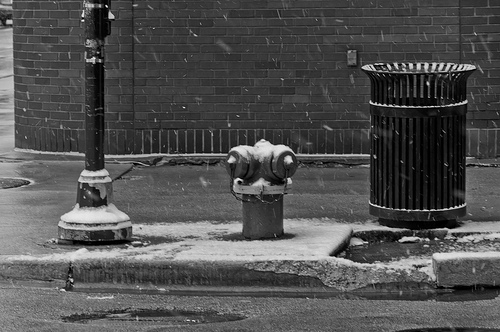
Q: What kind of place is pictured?
A: It is a sidewalk.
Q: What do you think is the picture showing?
A: It is showing a sidewalk.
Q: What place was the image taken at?
A: It was taken at the sidewalk.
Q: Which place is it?
A: It is a sidewalk.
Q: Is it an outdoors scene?
A: Yes, it is outdoors.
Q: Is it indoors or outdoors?
A: It is outdoors.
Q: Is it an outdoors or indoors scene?
A: It is outdoors.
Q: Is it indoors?
A: No, it is outdoors.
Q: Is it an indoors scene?
A: No, it is outdoors.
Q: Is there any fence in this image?
A: No, there are no fences.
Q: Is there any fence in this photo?
A: No, there are no fences.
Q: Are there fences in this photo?
A: No, there are no fences.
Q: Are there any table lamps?
A: No, there are no table lamps.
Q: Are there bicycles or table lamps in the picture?
A: No, there are no table lamps or bicycles.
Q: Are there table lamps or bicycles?
A: No, there are no table lamps or bicycles.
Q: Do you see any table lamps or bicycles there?
A: No, there are no table lamps or bicycles.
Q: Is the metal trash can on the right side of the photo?
A: Yes, the garbage bin is on the right of the image.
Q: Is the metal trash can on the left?
A: No, the trash bin is on the right of the image.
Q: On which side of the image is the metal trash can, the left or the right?
A: The garbage can is on the right of the image.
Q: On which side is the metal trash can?
A: The garbage can is on the right of the image.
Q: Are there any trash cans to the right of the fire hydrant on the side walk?
A: Yes, there is a trash can to the right of the fire hydrant.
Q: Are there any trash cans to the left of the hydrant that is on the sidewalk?
A: No, the trash can is to the right of the fire hydrant.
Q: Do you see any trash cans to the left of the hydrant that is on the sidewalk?
A: No, the trash can is to the right of the fire hydrant.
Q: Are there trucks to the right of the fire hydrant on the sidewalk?
A: No, there is a trash can to the right of the fire hydrant.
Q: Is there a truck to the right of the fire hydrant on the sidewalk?
A: No, there is a trash can to the right of the fire hydrant.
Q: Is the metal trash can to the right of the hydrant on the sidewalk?
A: Yes, the garbage bin is to the right of the hydrant.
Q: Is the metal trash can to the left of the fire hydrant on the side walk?
A: No, the trashcan is to the right of the fire hydrant.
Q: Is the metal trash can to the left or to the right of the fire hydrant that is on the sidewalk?
A: The trashcan is to the right of the hydrant.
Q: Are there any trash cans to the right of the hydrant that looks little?
A: Yes, there is a trash can to the right of the hydrant.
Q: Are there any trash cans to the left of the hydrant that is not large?
A: No, the trash can is to the right of the hydrant.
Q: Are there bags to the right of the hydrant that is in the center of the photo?
A: No, there is a trash can to the right of the hydrant.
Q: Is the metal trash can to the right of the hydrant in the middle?
A: Yes, the garbage can is to the right of the hydrant.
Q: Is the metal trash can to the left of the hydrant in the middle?
A: No, the garbage can is to the right of the fire hydrant.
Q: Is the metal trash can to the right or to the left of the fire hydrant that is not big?
A: The garbage can is to the right of the fire hydrant.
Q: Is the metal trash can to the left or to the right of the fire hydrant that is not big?
A: The garbage can is to the right of the fire hydrant.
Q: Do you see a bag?
A: No, there are no bags.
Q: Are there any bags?
A: No, there are no bags.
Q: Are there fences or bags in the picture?
A: No, there are no bags or fences.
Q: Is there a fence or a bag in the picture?
A: No, there are no bags or fences.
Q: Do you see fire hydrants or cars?
A: Yes, there is a fire hydrant.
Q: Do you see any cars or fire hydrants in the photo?
A: Yes, there is a fire hydrant.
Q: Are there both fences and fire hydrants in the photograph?
A: No, there is a fire hydrant but no fences.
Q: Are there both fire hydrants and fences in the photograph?
A: No, there is a fire hydrant but no fences.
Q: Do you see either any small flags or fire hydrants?
A: Yes, there is a small fire hydrant.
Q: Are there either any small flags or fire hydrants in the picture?
A: Yes, there is a small fire hydrant.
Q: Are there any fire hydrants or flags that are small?
A: Yes, the fire hydrant is small.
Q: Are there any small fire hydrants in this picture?
A: Yes, there is a small fire hydrant.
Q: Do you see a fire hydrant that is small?
A: Yes, there is a fire hydrant that is small.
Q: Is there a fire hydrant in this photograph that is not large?
A: Yes, there is a small fire hydrant.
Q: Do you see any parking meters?
A: No, there are no parking meters.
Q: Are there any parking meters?
A: No, there are no parking meters.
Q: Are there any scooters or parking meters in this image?
A: No, there are no parking meters or scooters.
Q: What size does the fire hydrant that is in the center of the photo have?
A: The hydrant has small size.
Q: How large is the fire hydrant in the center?
A: The hydrant is small.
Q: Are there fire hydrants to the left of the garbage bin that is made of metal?
A: Yes, there is a fire hydrant to the left of the garbage can.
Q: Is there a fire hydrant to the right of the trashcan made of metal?
A: No, the fire hydrant is to the left of the garbage can.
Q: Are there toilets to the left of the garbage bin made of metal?
A: No, there is a fire hydrant to the left of the trash can.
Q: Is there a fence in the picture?
A: No, there are no fences.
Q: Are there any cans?
A: Yes, there is a can.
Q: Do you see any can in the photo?
A: Yes, there is a can.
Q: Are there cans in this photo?
A: Yes, there is a can.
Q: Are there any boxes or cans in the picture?
A: Yes, there is a can.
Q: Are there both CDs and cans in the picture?
A: No, there is a can but no cds.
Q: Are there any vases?
A: No, there are no vases.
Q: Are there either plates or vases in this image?
A: No, there are no vases or plates.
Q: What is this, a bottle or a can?
A: This is a can.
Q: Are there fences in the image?
A: No, there are no fences.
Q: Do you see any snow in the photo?
A: Yes, there is snow.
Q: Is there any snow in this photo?
A: Yes, there is snow.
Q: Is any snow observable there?
A: Yes, there is snow.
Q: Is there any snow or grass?
A: Yes, there is snow.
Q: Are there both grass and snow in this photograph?
A: No, there is snow but no grass.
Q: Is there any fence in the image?
A: No, there are no fences.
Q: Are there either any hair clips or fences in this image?
A: No, there are no fences or hair clips.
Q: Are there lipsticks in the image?
A: No, there are no lipsticks.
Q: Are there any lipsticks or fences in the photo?
A: No, there are no lipsticks or fences.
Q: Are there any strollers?
A: No, there are no strollers.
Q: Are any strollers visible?
A: No, there are no strollers.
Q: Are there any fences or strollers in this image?
A: No, there are no strollers or fences.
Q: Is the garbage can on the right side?
A: Yes, the garbage can is on the right of the image.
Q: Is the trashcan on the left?
A: No, the trashcan is on the right of the image.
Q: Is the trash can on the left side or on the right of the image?
A: The trash can is on the right of the image.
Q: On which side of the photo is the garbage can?
A: The garbage can is on the right of the image.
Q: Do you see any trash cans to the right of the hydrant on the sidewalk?
A: Yes, there is a trash can to the right of the fire hydrant.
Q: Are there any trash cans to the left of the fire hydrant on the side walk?
A: No, the trash can is to the right of the fire hydrant.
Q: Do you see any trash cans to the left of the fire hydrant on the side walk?
A: No, the trash can is to the right of the fire hydrant.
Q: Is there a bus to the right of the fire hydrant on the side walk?
A: No, there is a trash can to the right of the fire hydrant.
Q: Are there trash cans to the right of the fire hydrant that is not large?
A: Yes, there is a trash can to the right of the hydrant.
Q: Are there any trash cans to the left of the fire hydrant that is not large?
A: No, the trash can is to the right of the hydrant.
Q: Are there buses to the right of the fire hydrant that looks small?
A: No, there is a trash can to the right of the fire hydrant.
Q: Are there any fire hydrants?
A: Yes, there is a fire hydrant.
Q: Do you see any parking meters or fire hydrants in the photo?
A: Yes, there is a fire hydrant.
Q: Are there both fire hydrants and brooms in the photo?
A: No, there is a fire hydrant but no brooms.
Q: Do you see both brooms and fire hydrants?
A: No, there is a fire hydrant but no brooms.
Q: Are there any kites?
A: No, there are no kites.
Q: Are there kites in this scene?
A: No, there are no kites.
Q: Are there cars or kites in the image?
A: No, there are no kites or cars.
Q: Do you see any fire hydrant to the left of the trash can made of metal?
A: Yes, there is a fire hydrant to the left of the trash can.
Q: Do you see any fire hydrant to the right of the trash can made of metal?
A: No, the fire hydrant is to the left of the garbage can.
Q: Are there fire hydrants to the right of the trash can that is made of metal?
A: No, the fire hydrant is to the left of the garbage can.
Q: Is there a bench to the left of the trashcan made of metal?
A: No, there is a fire hydrant to the left of the garbage bin.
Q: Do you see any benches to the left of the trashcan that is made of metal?
A: No, there is a fire hydrant to the left of the garbage bin.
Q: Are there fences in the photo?
A: No, there are no fences.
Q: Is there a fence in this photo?
A: No, there are no fences.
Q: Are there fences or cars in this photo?
A: No, there are no fences or cars.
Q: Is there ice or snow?
A: Yes, there is snow.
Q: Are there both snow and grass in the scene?
A: No, there is snow but no grass.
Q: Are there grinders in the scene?
A: No, there are no grinders.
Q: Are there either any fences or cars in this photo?
A: No, there are no cars or fences.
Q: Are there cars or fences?
A: No, there are no cars or fences.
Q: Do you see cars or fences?
A: No, there are no cars or fences.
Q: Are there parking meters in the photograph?
A: No, there are no parking meters.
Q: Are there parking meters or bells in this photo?
A: No, there are no parking meters or bells.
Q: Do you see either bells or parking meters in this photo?
A: No, there are no parking meters or bells.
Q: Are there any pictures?
A: No, there are no pictures.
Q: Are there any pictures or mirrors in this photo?
A: No, there are no pictures or mirrors.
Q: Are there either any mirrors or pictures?
A: No, there are no pictures or mirrors.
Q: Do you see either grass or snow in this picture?
A: Yes, there is snow.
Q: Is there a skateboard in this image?
A: No, there are no skateboards.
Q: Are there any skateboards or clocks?
A: No, there are no skateboards or clocks.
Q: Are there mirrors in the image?
A: No, there are no mirrors.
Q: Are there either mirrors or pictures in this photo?
A: No, there are no mirrors or pictures.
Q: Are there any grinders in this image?
A: No, there are no grinders.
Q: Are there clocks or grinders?
A: No, there are no grinders or clocks.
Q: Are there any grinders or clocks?
A: No, there are no grinders or clocks.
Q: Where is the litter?
A: The litter is on the sidewalk.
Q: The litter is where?
A: The litter is on the sidewalk.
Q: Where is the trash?
A: The litter is on the sidewalk.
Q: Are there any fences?
A: No, there are no fences.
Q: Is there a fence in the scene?
A: No, there are no fences.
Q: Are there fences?
A: No, there are no fences.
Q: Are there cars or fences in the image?
A: No, there are no fences or cars.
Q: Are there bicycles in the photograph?
A: No, there are no bicycles.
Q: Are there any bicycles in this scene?
A: No, there are no bicycles.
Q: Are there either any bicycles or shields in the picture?
A: No, there are no bicycles or shields.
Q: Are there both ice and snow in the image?
A: No, there is snow but no ice.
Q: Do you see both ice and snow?
A: No, there is snow but no ice.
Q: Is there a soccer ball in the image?
A: No, there are no soccer balls.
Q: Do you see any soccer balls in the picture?
A: No, there are no soccer balls.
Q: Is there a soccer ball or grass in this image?
A: No, there are no soccer balls or grass.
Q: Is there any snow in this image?
A: Yes, there is snow.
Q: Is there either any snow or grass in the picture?
A: Yes, there is snow.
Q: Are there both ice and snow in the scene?
A: No, there is snow but no ice.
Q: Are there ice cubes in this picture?
A: No, there are no ice cubes.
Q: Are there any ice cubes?
A: No, there are no ice cubes.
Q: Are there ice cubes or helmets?
A: No, there are no ice cubes or helmets.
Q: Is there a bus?
A: No, there are no buses.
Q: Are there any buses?
A: No, there are no buses.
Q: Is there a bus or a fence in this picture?
A: No, there are no buses or fences.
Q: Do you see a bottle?
A: No, there are no bottles.